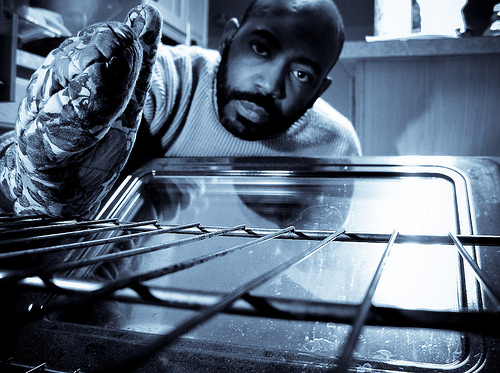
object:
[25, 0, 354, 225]
man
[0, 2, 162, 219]
oven mitt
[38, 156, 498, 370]
oven door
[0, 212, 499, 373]
oven rack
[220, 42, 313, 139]
beard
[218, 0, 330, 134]
face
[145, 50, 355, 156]
sweater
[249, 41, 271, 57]
eye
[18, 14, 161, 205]
hand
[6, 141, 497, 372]
oven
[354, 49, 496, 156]
cabinet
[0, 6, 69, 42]
stuff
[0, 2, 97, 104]
shelves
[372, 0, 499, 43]
window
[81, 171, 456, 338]
window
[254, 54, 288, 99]
nose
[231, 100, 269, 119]
lips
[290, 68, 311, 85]
left eye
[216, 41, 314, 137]
mustache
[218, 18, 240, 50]
right ear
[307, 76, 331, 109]
left ear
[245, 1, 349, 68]
bald head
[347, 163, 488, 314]
glare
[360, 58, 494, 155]
panel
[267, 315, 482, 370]
marks